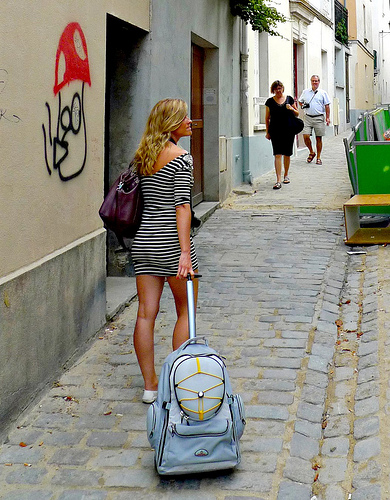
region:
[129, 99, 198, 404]
a woman in a zebra stripe dress.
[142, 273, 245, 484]
a blue bag of luggage.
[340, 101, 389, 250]
a green bin in an alley.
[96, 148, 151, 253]
a purple purse.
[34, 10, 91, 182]
graffiti on the side of a wall.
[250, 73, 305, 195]
a woman dressed in black.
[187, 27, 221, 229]
an entrance to a buildingl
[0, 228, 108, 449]
A cement section of a building.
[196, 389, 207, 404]
a latch on a bag.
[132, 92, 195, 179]
a woman with blonde hair.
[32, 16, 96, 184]
Graffiti painted on the wall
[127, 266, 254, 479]
Pull along bag with wheels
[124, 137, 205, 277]
Short dress worn by a woman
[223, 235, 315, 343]
Sidewalk made from cobblestone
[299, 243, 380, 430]
Gutter made of cobblestone next to cobblestone sidewalk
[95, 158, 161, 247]
Bag being carried by a female tourist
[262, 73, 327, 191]
Pedestrians on the sidewalk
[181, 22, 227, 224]
Doorway in the building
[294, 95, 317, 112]
Camera being carried by tourist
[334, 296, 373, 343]
Leaves fallen from the trees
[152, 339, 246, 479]
blue and yellow rolling backpack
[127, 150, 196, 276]
white and black striped dress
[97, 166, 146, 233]
red leather hobo bag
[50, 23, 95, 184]
graffiti on stone wall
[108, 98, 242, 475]
woman going on vacation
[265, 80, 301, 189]
woman wearing black dress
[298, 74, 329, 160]
man wearing blue shirt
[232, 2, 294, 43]
limbs with green leaves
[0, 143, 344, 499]
grey brick walk way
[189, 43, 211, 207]
shiny brown entry door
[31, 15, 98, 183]
red and black graffiti on a wall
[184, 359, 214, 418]
yellow cording on the backpack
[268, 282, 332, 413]
gray cobblestones in the sidewalk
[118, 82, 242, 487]
a young woman pulling a backpack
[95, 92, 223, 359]
a woman wearing a black and white striped dress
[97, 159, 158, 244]
a purple leather fashion bag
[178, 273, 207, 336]
a metal pull handle on the backpack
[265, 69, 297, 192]
an older woman wearing black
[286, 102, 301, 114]
a hand clutching a purse strap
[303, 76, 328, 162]
an older man carrying a camera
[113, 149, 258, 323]
the girl is wearing stripe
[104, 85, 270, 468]
the girl is wearing stripe